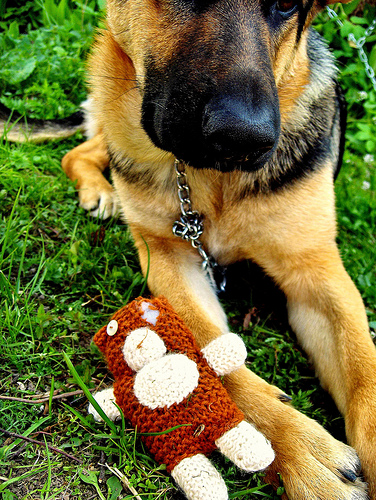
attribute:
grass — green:
[8, 179, 85, 260]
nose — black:
[204, 111, 279, 164]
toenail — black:
[330, 443, 368, 495]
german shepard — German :
[64, 0, 373, 498]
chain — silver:
[160, 156, 226, 284]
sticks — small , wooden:
[1, 374, 97, 415]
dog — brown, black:
[48, 6, 369, 308]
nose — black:
[197, 98, 324, 169]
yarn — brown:
[70, 305, 277, 488]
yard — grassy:
[24, 95, 368, 402]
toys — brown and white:
[57, 336, 291, 499]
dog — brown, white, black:
[60, 0, 373, 498]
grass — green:
[1, 223, 92, 411]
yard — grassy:
[0, 0, 376, 498]